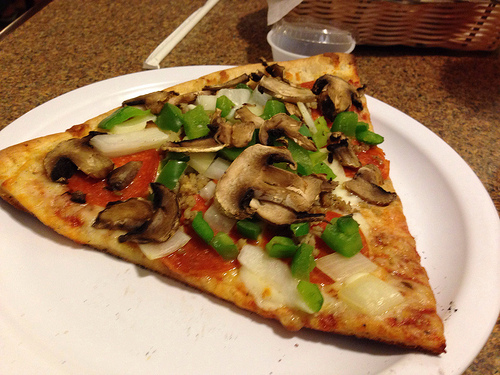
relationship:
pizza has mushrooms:
[2, 50, 447, 358] [209, 138, 314, 220]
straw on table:
[140, 0, 224, 70] [1, 1, 500, 374]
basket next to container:
[282, 1, 499, 55] [265, 27, 356, 62]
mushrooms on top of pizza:
[209, 138, 314, 220] [2, 50, 447, 358]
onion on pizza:
[335, 273, 405, 320] [2, 50, 447, 358]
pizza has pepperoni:
[2, 50, 447, 358] [64, 149, 160, 211]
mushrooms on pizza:
[209, 138, 314, 220] [2, 50, 447, 358]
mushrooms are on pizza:
[209, 138, 314, 220] [2, 50, 447, 358]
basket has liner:
[282, 1, 499, 55] [265, 1, 301, 29]